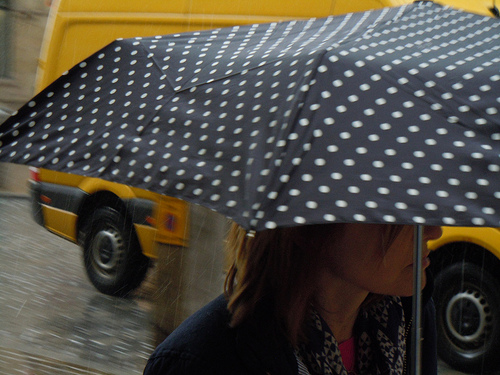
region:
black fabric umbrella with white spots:
[34, 19, 486, 278]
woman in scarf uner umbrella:
[142, 172, 452, 366]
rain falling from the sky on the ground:
[6, 214, 79, 341]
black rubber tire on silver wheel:
[59, 185, 159, 297]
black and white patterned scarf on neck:
[283, 295, 425, 374]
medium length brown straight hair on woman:
[214, 205, 407, 351]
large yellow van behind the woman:
[22, 5, 482, 341]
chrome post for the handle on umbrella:
[390, 197, 435, 368]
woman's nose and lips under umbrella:
[415, 196, 456, 296]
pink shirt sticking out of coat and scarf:
[308, 319, 389, 369]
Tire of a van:
[70, 176, 153, 301]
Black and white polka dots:
[0, 10, 497, 241]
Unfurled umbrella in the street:
[0, 0, 498, 240]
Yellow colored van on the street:
[13, 0, 498, 374]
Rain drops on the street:
[0, 170, 226, 371]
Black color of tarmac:
[1, 187, 166, 372]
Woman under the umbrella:
[135, 186, 455, 372]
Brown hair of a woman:
[218, 213, 410, 335]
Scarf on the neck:
[298, 294, 410, 374]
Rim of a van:
[84, 223, 124, 278]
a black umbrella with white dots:
[0, 0, 496, 235]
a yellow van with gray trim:
[22, 0, 497, 370]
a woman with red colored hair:
[140, 223, 441, 373]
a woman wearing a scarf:
[141, 220, 438, 371]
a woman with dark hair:
[140, 226, 435, 372]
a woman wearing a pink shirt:
[137, 225, 438, 371]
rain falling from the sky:
[0, 162, 225, 372]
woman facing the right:
[140, 222, 445, 372]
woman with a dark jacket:
[141, 221, 449, 371]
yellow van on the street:
[16, 15, 490, 283]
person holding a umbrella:
[183, 98, 444, 360]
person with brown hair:
[221, 222, 323, 349]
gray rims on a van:
[91, 217, 128, 282]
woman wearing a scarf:
[298, 300, 423, 371]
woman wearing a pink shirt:
[318, 329, 375, 373]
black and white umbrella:
[116, 9, 472, 185]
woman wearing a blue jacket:
[151, 308, 236, 370]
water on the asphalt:
[13, 270, 151, 373]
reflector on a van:
[26, 168, 49, 190]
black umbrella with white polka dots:
[5, 5, 490, 232]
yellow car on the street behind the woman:
[10, 8, 495, 363]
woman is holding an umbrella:
[6, 5, 487, 370]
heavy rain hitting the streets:
[6, 202, 187, 368]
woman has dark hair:
[227, 190, 438, 338]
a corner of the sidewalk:
[0, 348, 110, 371]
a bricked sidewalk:
[0, 342, 110, 369]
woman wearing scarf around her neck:
[285, 268, 412, 371]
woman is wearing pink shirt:
[331, 335, 363, 372]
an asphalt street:
[1, 195, 161, 374]